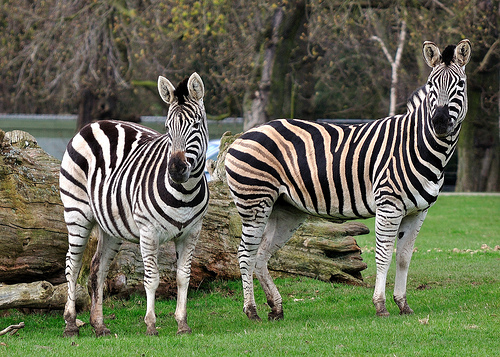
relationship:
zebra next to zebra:
[52, 73, 210, 335] [225, 40, 473, 320]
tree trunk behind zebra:
[2, 126, 368, 291] [52, 73, 210, 335]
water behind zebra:
[1, 109, 245, 169] [52, 73, 210, 335]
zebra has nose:
[52, 73, 210, 335] [168, 151, 189, 179]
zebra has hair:
[52, 73, 210, 335] [172, 79, 191, 103]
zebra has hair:
[225, 40, 473, 320] [439, 41, 453, 64]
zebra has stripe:
[225, 40, 473, 320] [268, 117, 321, 213]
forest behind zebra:
[5, 1, 499, 193] [225, 40, 473, 320]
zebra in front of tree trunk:
[52, 73, 210, 335] [2, 126, 368, 291]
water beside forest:
[1, 109, 245, 169] [5, 1, 499, 193]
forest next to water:
[5, 1, 499, 193] [1, 109, 245, 169]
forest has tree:
[5, 1, 499, 193] [232, 3, 316, 125]